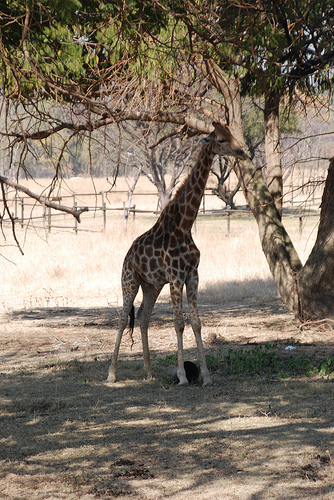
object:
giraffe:
[106, 118, 252, 390]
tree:
[1, 0, 333, 322]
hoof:
[174, 374, 191, 389]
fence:
[4, 190, 334, 234]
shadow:
[3, 276, 294, 331]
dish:
[172, 360, 200, 385]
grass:
[157, 346, 332, 371]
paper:
[283, 343, 297, 352]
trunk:
[297, 146, 334, 327]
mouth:
[232, 150, 255, 164]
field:
[0, 170, 115, 305]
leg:
[105, 274, 138, 385]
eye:
[217, 135, 225, 146]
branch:
[2, 107, 221, 158]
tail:
[126, 302, 138, 352]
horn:
[224, 123, 230, 132]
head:
[207, 120, 249, 164]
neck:
[153, 148, 214, 227]